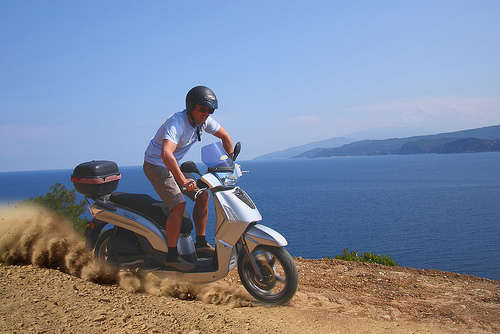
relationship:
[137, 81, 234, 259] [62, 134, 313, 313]
man riding scooter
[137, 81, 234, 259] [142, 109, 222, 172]
man wearing shirt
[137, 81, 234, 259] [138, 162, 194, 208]
man wearing shorts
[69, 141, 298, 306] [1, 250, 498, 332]
moped on road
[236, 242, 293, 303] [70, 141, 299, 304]
tire of scooter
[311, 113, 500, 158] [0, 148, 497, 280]
mountains near ocean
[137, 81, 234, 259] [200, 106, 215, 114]
man wearing sunglasses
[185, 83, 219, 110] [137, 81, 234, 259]
helmet on a man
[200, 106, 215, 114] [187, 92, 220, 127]
sunglasses on a face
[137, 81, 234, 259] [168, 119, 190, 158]
man in shirt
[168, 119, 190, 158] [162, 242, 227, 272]
shirt and shoes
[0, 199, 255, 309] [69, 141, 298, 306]
dirt plume under a moped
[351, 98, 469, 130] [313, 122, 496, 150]
white clouds over mountain range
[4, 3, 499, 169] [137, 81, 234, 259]
sky behind man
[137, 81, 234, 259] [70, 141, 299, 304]
man on scooter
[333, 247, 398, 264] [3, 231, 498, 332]
grass beside dirt road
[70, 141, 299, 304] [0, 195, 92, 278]
scooter causing dirt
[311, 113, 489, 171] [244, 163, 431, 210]
mountains next to water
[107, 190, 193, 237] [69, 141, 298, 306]
black seat on a moped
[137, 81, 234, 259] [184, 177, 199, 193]
man wearing hand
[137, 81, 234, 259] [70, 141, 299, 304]
man riding scooter